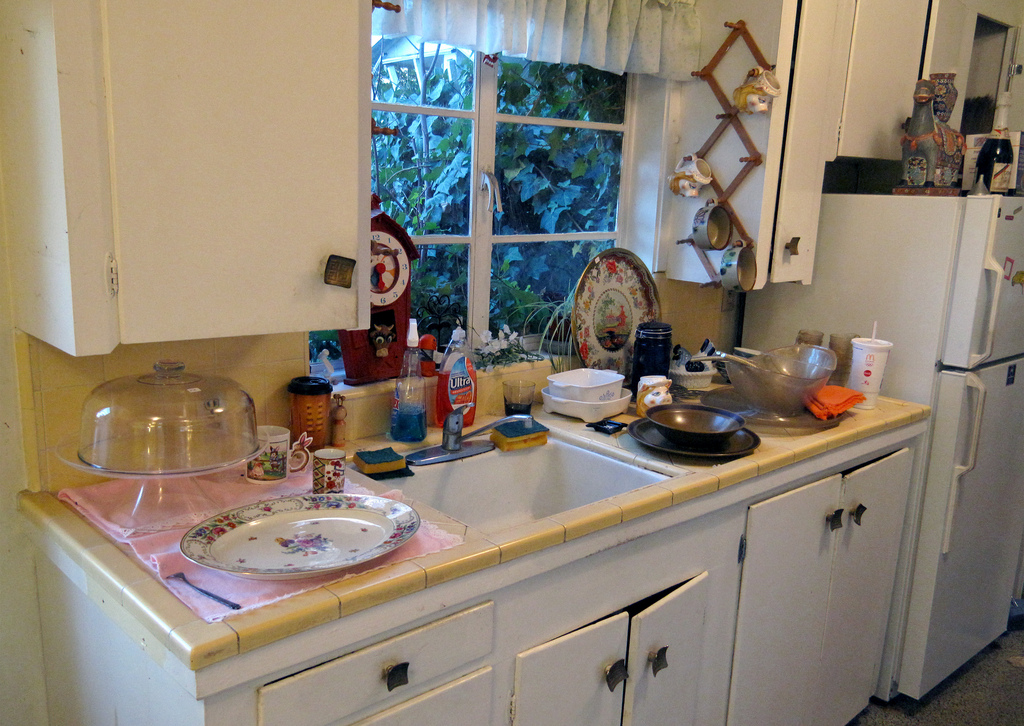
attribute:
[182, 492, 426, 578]
plate — white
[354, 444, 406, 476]
sponge — blue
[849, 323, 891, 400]
cup — white plastic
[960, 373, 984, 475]
handle — White 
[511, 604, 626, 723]
cabinet door —  cabinet ,   slightly opened.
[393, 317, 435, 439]
plastic bottle — plastic., counter.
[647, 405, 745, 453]
bowl — gray 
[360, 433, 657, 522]
sink. — on top 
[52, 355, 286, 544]
cover. —  cake 